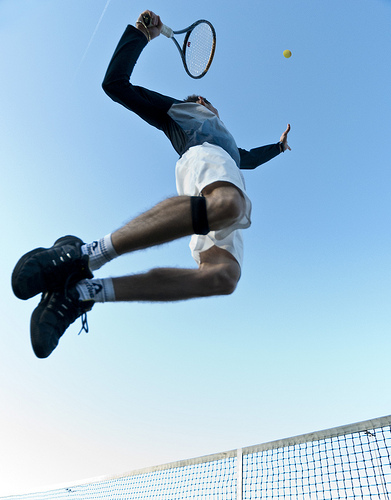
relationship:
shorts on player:
[178, 148, 249, 193] [13, 12, 291, 360]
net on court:
[18, 416, 386, 498] [368, 493, 380, 498]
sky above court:
[1, 2, 390, 414] [368, 493, 380, 498]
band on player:
[190, 196, 210, 237] [13, 12, 291, 360]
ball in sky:
[283, 50, 295, 60] [1, 2, 390, 414]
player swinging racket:
[13, 12, 291, 360] [155, 20, 216, 79]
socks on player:
[87, 238, 118, 303] [13, 12, 291, 360]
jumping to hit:
[13, 12, 291, 360] [185, 22, 292, 76]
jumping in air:
[25, 190, 289, 341] [5, 0, 391, 406]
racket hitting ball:
[155, 20, 216, 79] [283, 50, 295, 60]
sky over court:
[1, 2, 390, 414] [368, 493, 380, 498]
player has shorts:
[13, 12, 291, 360] [178, 148, 249, 193]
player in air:
[13, 12, 291, 360] [5, 0, 391, 406]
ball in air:
[283, 50, 295, 60] [5, 0, 391, 406]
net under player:
[18, 416, 386, 498] [13, 12, 291, 360]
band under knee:
[190, 196, 210, 237] [209, 192, 242, 232]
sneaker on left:
[29, 290, 91, 361] [33, 297, 89, 355]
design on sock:
[86, 282, 103, 298] [83, 277, 117, 304]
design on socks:
[86, 240, 104, 257] [77, 233, 120, 273]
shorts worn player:
[178, 148, 249, 193] [13, 12, 291, 360]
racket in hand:
[155, 20, 216, 79] [135, 11, 165, 40]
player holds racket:
[13, 12, 291, 360] [155, 20, 216, 79]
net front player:
[18, 416, 386, 498] [13, 12, 291, 360]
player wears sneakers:
[13, 12, 291, 360] [13, 233, 92, 358]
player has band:
[13, 12, 291, 360] [190, 196, 210, 237]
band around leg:
[190, 196, 210, 237] [122, 194, 240, 251]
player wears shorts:
[13, 12, 291, 360] [178, 148, 249, 193]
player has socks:
[13, 12, 291, 360] [87, 238, 118, 303]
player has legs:
[13, 12, 291, 360] [115, 194, 212, 304]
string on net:
[223, 462, 385, 499] [18, 416, 386, 498]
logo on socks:
[85, 238, 105, 300] [87, 238, 118, 303]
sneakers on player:
[13, 233, 92, 358] [13, 12, 291, 360]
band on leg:
[190, 196, 210, 237] [122, 194, 240, 251]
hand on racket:
[135, 11, 165, 40] [155, 20, 216, 79]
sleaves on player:
[240, 144, 280, 169] [13, 12, 291, 360]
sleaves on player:
[98, 23, 170, 120] [13, 12, 291, 360]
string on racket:
[190, 35, 212, 71] [155, 20, 216, 79]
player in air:
[13, 12, 291, 360] [3, 3, 388, 497]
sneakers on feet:
[13, 233, 92, 358] [11, 224, 97, 365]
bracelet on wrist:
[138, 17, 155, 42] [129, 14, 159, 43]